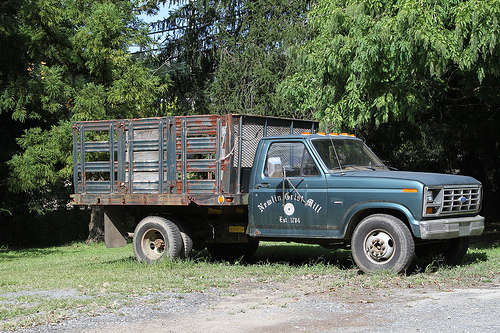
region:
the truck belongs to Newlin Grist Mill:
[240, 136, 337, 258]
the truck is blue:
[257, 126, 434, 251]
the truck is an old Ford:
[280, 131, 485, 285]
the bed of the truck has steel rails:
[65, 96, 261, 215]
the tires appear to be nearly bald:
[109, 218, 202, 277]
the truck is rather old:
[60, 87, 487, 309]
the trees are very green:
[276, 14, 483, 106]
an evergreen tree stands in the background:
[164, 15, 282, 92]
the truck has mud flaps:
[84, 185, 138, 250]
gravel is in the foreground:
[76, 277, 281, 332]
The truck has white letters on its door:
[257, 190, 362, 268]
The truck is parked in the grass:
[61, 106, 474, 314]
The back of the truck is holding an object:
[68, 113, 267, 235]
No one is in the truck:
[249, 126, 496, 307]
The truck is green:
[249, 129, 493, 276]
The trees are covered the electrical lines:
[7, 5, 488, 160]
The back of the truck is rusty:
[70, 117, 275, 232]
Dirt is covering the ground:
[166, 275, 477, 323]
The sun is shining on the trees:
[261, 0, 481, 95]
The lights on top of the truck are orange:
[298, 123, 383, 156]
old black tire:
[343, 197, 421, 279]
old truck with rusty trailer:
[63, 91, 498, 327]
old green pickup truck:
[63, 87, 499, 283]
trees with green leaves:
[224, 1, 476, 133]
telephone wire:
[116, 3, 288, 72]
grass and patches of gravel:
[141, 250, 353, 331]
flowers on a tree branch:
[13, 42, 91, 111]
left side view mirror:
[250, 125, 320, 225]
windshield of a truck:
[307, 126, 402, 172]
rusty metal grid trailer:
[73, 108, 248, 218]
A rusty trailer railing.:
[67, 110, 227, 205]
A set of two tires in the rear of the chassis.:
[125, 213, 196, 267]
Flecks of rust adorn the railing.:
[173, 116, 231, 193]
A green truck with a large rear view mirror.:
[245, 131, 488, 283]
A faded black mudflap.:
[99, 202, 129, 254]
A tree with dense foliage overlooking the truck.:
[273, 1, 498, 141]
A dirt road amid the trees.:
[43, 286, 496, 330]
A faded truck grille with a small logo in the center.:
[422, 184, 481, 215]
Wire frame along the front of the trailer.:
[233, 126, 314, 166]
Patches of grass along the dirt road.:
[1, 251, 107, 329]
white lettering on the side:
[255, 191, 326, 231]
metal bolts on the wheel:
[374, 234, 389, 256]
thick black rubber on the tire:
[163, 225, 178, 263]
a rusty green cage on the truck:
[81, 129, 226, 194]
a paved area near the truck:
[346, 300, 448, 331]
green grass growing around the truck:
[56, 242, 123, 298]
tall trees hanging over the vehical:
[249, 0, 466, 109]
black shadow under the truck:
[231, 251, 328, 272]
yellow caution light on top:
[300, 126, 362, 136]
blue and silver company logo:
[453, 192, 474, 207]